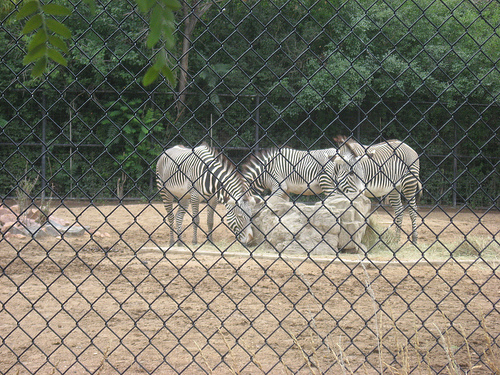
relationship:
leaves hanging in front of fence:
[12, 4, 71, 76] [7, 1, 499, 372]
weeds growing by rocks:
[9, 163, 66, 222] [9, 215, 98, 241]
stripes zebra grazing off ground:
[155, 140, 262, 248] [102, 252, 449, 327]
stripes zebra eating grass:
[155, 140, 262, 248] [403, 242, 445, 254]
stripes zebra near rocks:
[155, 140, 262, 248] [252, 193, 372, 258]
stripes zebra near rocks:
[241, 143, 340, 203] [252, 193, 372, 258]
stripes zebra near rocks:
[328, 135, 423, 246] [252, 193, 372, 258]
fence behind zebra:
[7, 1, 499, 372] [239, 136, 361, 196]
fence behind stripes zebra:
[7, 1, 499, 372] [155, 140, 262, 248]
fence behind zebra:
[7, 1, 499, 372] [357, 142, 423, 232]